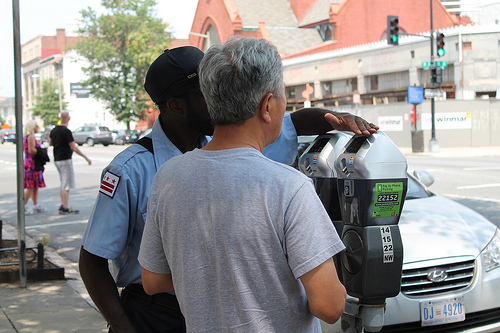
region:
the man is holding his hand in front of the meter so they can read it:
[328, 108, 393, 183]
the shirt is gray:
[186, 180, 250, 241]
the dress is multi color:
[24, 147, 34, 174]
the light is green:
[385, 30, 405, 47]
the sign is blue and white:
[403, 75, 429, 112]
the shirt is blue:
[124, 158, 146, 190]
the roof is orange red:
[346, 12, 369, 31]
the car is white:
[426, 217, 466, 245]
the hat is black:
[149, 45, 183, 77]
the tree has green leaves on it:
[93, 10, 143, 67]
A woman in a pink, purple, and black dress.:
[20, 112, 53, 219]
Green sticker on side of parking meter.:
[370, 176, 407, 221]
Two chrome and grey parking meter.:
[301, 125, 404, 331]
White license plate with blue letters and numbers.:
[417, 297, 469, 328]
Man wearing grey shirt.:
[140, 39, 349, 331]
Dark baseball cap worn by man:
[142, 43, 202, 105]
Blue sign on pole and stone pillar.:
[406, 83, 428, 157]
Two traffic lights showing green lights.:
[385, 10, 448, 59]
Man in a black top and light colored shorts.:
[46, 111, 89, 217]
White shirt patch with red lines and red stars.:
[96, 167, 121, 198]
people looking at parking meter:
[79, 31, 447, 331]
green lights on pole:
[373, 8, 471, 149]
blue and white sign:
[397, 82, 431, 104]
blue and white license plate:
[409, 285, 477, 332]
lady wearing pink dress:
[17, 118, 62, 227]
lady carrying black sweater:
[10, 115, 60, 210]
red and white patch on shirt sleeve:
[87, 138, 147, 280]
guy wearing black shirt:
[47, 107, 97, 205]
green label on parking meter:
[336, 125, 408, 309]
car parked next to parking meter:
[287, 113, 497, 330]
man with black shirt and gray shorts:
[44, 109, 94, 216]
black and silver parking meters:
[297, 121, 409, 301]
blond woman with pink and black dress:
[14, 117, 51, 215]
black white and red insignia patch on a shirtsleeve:
[93, 165, 122, 202]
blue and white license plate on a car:
[408, 290, 475, 330]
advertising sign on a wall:
[418, 109, 473, 131]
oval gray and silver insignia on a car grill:
[423, 265, 452, 289]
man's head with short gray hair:
[196, 30, 288, 151]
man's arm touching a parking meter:
[290, 105, 380, 140]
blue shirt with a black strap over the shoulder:
[77, 118, 197, 288]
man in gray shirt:
[136, 34, 348, 331]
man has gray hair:
[197, 34, 283, 128]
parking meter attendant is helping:
[76, 44, 381, 331]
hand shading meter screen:
[322, 110, 379, 154]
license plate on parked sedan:
[340, 170, 499, 330]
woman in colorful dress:
[18, 120, 50, 215]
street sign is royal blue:
[406, 85, 425, 105]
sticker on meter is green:
[371, 180, 402, 216]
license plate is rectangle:
[418, 295, 465, 327]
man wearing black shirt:
[48, 111, 92, 213]